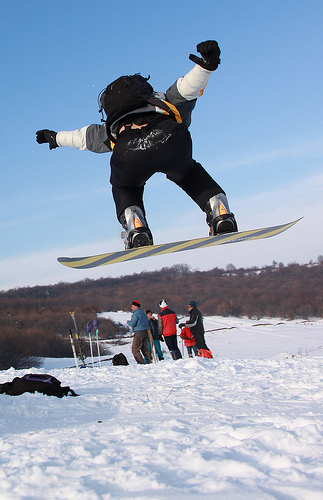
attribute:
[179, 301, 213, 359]
person — standing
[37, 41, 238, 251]
snow boarder — flying through air, performing trick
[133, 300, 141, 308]
cap — red, black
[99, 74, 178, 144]
back pack — black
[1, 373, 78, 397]
bag — black, large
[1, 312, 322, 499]
snow — clumpy, thick, white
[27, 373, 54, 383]
stripes — purple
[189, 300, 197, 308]
cap — blue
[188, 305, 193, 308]
goggles — orange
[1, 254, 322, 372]
woods — dead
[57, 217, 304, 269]
snowboard — yellow, gray, black, in the air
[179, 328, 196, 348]
coat — red, white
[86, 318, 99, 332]
gloves — purple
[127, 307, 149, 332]
coat — blue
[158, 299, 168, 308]
cap — white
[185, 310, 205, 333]
coat — black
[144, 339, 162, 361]
pants — teal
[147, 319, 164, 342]
coat — brown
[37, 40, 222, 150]
gloves — black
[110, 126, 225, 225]
pants — black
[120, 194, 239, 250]
shoes — black, gray